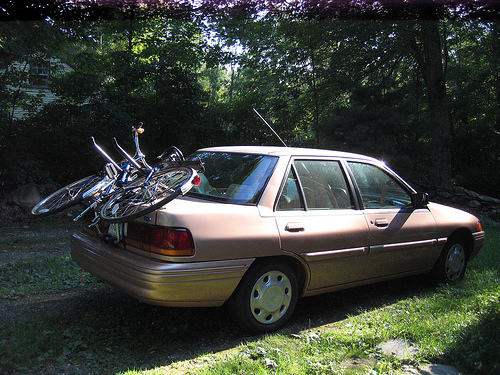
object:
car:
[69, 145, 484, 333]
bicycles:
[30, 120, 207, 228]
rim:
[249, 269, 292, 323]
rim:
[443, 243, 465, 281]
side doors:
[276, 155, 436, 291]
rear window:
[197, 150, 277, 206]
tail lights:
[82, 206, 194, 260]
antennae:
[251, 105, 290, 148]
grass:
[4, 244, 499, 374]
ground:
[1, 199, 497, 374]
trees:
[0, 0, 499, 122]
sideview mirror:
[409, 191, 429, 207]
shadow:
[2, 275, 358, 374]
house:
[2, 37, 102, 128]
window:
[27, 56, 53, 91]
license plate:
[103, 220, 128, 237]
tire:
[225, 256, 298, 332]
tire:
[431, 237, 467, 284]